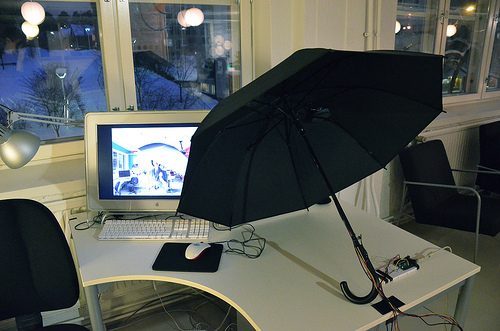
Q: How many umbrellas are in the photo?
A: One.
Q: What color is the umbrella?
A: Black.